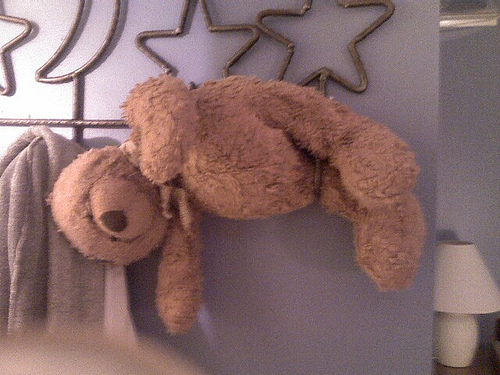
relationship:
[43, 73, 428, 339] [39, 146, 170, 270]
teddy bear has head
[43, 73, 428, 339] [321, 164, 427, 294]
teddy bear has leg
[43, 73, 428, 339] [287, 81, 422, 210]
teddy bear has leg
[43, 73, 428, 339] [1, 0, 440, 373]
teddy bear hanging from wall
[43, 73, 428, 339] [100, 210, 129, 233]
teddy bear has nose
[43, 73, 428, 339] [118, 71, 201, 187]
teddy bear has arm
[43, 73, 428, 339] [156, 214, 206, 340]
teddy bear has arm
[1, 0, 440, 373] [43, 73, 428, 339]
wall behind teddy bear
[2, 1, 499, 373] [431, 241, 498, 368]
room has lamp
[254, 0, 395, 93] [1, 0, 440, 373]
star hanging on wall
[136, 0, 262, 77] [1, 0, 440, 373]
star hanging on wall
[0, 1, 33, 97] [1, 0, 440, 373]
star hanging on wall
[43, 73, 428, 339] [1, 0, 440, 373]
teddy bear hanging on wall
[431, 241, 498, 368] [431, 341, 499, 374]
lamp sitting on table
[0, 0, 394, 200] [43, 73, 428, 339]
rod holds teddy bear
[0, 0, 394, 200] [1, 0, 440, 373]
rod attached to wall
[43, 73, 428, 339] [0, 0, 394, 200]
teddy bear hanging on rod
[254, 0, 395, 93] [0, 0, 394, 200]
star part of rod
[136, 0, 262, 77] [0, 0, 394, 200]
star part of rod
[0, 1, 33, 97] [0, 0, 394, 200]
star part of rod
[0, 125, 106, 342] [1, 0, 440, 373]
cloth hanging from wall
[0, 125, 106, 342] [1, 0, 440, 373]
cloth hanging on wall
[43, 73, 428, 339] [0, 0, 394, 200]
teddy bear held by rod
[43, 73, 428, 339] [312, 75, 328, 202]
teddy bear hanging on hook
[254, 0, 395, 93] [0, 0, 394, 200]
star visible on rod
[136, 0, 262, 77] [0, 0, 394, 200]
star visible on rod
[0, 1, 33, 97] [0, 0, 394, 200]
star visible on rod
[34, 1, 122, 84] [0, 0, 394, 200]
moon visible on rod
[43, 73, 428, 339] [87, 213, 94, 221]
teddy bear has eye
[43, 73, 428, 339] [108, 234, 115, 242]
teddy bear has eye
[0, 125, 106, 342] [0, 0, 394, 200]
cloth hangs on rod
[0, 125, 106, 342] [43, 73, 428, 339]
cloth hangs next to teddy bear